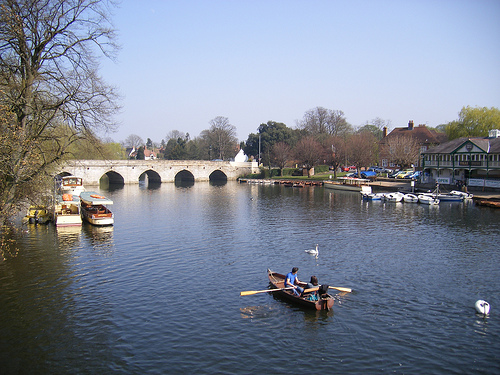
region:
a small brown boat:
[221, 226, 410, 356]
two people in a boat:
[271, 262, 363, 326]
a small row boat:
[206, 243, 409, 363]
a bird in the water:
[290, 230, 352, 272]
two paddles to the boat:
[212, 269, 379, 316]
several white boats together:
[351, 175, 476, 227]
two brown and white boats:
[41, 180, 136, 244]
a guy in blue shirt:
[273, 260, 318, 310]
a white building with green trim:
[396, 117, 496, 217]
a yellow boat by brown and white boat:
[15, 185, 62, 237]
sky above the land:
[162, 21, 314, 92]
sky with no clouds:
[191, 11, 332, 66]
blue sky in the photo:
[207, 13, 406, 93]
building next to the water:
[409, 120, 496, 184]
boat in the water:
[218, 233, 353, 343]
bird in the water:
[288, 229, 340, 272]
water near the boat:
[156, 217, 245, 267]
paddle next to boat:
[222, 277, 287, 309]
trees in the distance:
[251, 114, 360, 167]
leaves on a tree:
[248, 117, 294, 149]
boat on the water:
[232, 255, 337, 316]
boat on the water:
[435, 190, 477, 207]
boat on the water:
[362, 191, 384, 203]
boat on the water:
[81, 202, 111, 233]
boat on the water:
[52, 198, 90, 228]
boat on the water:
[357, 182, 388, 205]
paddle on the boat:
[239, 287, 267, 308]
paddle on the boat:
[332, 282, 357, 296]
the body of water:
[156, 304, 196, 345]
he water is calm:
[147, 230, 228, 281]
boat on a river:
[238, 250, 346, 326]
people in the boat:
[285, 265, 316, 295]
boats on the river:
[365, 180, 455, 210]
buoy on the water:
[470, 285, 490, 321]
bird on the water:
[295, 227, 330, 259]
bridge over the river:
[85, 147, 245, 192]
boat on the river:
[76, 181, 111, 227]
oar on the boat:
[237, 282, 283, 312]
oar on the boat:
[337, 276, 354, 297]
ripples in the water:
[379, 283, 441, 338]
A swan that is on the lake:
[472, 291, 497, 316]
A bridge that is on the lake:
[60, 155, 254, 205]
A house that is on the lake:
[402, 122, 497, 179]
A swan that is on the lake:
[300, 243, 332, 258]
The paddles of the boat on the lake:
[238, 282, 363, 294]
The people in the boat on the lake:
[285, 272, 325, 307]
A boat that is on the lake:
[255, 271, 353, 328]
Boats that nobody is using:
[15, 182, 122, 242]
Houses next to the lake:
[381, 126, 498, 188]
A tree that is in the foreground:
[2, 0, 120, 312]